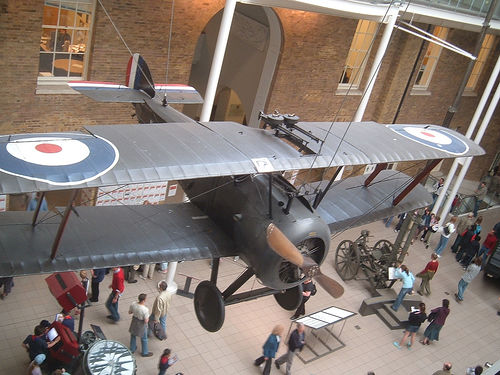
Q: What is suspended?
A: The model airplane.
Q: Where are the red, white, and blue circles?
A: On the wing.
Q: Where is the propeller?
A: In the front of the plane.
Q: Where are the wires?
A: Attached to the plane.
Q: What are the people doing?
A: Touring.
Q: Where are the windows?
A: On the brown wall.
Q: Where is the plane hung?
A: In a museum.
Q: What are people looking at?
A: Displays.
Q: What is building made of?
A: Bricks.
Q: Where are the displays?
A: In museum.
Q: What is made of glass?
A: Windows.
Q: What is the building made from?
A: Bricks.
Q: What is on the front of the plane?
A: A propeller.